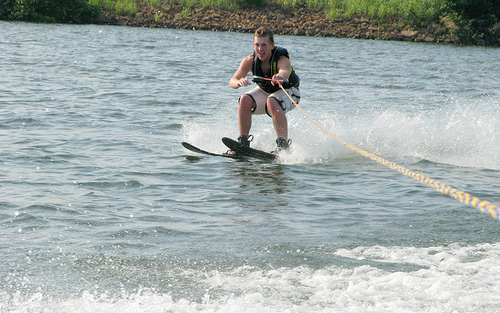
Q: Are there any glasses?
A: No, there are no glasses.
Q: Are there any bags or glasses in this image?
A: No, there are no glasses or bags.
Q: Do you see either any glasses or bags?
A: No, there are no glasses or bags.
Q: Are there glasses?
A: No, there are no glasses.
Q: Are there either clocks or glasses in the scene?
A: No, there are no glasses or clocks.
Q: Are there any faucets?
A: No, there are no faucets.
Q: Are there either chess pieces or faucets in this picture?
A: No, there are no faucets or chess pieces.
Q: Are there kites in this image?
A: No, there are no kites.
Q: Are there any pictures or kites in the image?
A: No, there are no kites or pictures.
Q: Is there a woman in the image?
A: No, there are no women.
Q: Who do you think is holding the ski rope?
A: The man is holding the rope.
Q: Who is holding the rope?
A: The man is holding the rope.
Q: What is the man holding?
A: The man is holding the rope.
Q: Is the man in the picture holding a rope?
A: Yes, the man is holding a rope.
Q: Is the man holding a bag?
A: No, the man is holding a rope.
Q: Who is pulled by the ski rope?
A: The man is pulled by the rope.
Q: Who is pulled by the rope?
A: The man is pulled by the rope.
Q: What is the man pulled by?
A: The man is pulled by the rope.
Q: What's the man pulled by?
A: The man is pulled by the rope.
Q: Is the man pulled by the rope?
A: Yes, the man is pulled by the rope.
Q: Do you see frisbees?
A: No, there are no frisbees.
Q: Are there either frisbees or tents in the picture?
A: No, there are no frisbees or tents.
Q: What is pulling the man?
A: The rope is pulling the man.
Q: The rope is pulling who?
A: The rope is pulling the man.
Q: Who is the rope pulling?
A: The rope is pulling the man.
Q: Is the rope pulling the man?
A: Yes, the rope is pulling the man.